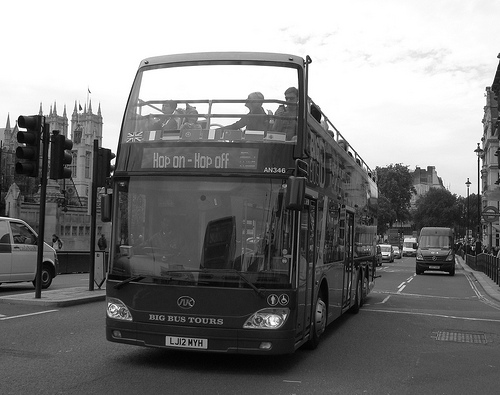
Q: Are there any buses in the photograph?
A: Yes, there is a bus.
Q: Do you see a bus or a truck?
A: Yes, there is a bus.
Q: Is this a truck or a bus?
A: This is a bus.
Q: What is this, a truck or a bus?
A: This is a bus.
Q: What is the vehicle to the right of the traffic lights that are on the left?
A: The vehicle is a bus.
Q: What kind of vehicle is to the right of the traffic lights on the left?
A: The vehicle is a bus.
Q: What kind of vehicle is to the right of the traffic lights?
A: The vehicle is a bus.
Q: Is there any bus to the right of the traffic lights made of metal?
A: Yes, there is a bus to the right of the traffic lights.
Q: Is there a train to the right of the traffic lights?
A: No, there is a bus to the right of the traffic lights.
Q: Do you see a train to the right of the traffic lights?
A: No, there is a bus to the right of the traffic lights.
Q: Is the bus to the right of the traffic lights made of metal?
A: Yes, the bus is to the right of the traffic lights.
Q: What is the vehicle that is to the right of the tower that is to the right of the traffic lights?
A: The vehicle is a bus.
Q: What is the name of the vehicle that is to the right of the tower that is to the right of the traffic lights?
A: The vehicle is a bus.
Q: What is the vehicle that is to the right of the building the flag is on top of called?
A: The vehicle is a bus.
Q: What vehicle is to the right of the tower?
A: The vehicle is a bus.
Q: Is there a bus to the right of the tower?
A: Yes, there is a bus to the right of the tower.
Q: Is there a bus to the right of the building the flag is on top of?
A: Yes, there is a bus to the right of the tower.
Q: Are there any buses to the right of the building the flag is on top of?
A: Yes, there is a bus to the right of the tower.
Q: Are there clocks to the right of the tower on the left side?
A: No, there is a bus to the right of the tower.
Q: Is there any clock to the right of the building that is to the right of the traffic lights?
A: No, there is a bus to the right of the tower.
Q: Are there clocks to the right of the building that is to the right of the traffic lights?
A: No, there is a bus to the right of the tower.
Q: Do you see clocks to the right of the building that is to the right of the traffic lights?
A: No, there is a bus to the right of the tower.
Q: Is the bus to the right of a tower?
A: Yes, the bus is to the right of a tower.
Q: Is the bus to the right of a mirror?
A: No, the bus is to the right of a tower.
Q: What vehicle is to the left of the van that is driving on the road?
A: The vehicle is a bus.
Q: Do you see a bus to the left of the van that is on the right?
A: Yes, there is a bus to the left of the van.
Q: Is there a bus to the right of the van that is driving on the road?
A: No, the bus is to the left of the van.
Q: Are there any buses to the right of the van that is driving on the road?
A: No, the bus is to the left of the van.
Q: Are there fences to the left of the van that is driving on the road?
A: No, there is a bus to the left of the van.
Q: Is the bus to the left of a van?
A: Yes, the bus is to the left of a van.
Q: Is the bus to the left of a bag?
A: No, the bus is to the left of a van.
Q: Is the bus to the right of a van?
A: No, the bus is to the left of a van.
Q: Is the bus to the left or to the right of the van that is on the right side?
A: The bus is to the left of the van.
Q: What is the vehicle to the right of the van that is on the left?
A: The vehicle is a bus.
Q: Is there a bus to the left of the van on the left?
A: No, the bus is to the right of the van.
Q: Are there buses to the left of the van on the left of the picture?
A: No, the bus is to the right of the van.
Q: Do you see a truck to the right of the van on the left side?
A: No, there is a bus to the right of the van.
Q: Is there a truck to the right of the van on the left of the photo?
A: No, there is a bus to the right of the van.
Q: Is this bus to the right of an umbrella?
A: No, the bus is to the right of a van.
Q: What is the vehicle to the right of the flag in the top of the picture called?
A: The vehicle is a bus.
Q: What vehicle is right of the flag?
A: The vehicle is a bus.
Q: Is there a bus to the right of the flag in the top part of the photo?
A: Yes, there is a bus to the right of the flag.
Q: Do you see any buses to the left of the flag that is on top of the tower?
A: No, the bus is to the right of the flag.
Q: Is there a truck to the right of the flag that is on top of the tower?
A: No, there is a bus to the right of the flag.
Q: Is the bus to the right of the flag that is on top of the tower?
A: Yes, the bus is to the right of the flag.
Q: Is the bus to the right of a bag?
A: No, the bus is to the right of the flag.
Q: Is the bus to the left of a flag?
A: No, the bus is to the right of a flag.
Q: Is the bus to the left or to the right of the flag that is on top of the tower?
A: The bus is to the right of the flag.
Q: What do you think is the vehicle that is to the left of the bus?
A: The vehicle is a van.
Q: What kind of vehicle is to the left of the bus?
A: The vehicle is a van.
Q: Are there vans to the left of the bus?
A: Yes, there is a van to the left of the bus.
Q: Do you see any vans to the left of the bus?
A: Yes, there is a van to the left of the bus.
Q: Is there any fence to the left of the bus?
A: No, there is a van to the left of the bus.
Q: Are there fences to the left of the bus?
A: No, there is a van to the left of the bus.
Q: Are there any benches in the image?
A: No, there are no benches.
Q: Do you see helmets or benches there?
A: No, there are no benches or helmets.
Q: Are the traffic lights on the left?
A: Yes, the traffic lights are on the left of the image.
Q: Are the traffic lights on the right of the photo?
A: No, the traffic lights are on the left of the image.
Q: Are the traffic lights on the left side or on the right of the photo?
A: The traffic lights are on the left of the image.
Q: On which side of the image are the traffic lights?
A: The traffic lights are on the left of the image.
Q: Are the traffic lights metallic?
A: Yes, the traffic lights are metallic.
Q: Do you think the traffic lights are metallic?
A: Yes, the traffic lights are metallic.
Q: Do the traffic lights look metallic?
A: Yes, the traffic lights are metallic.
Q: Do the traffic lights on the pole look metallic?
A: Yes, the traffic lights are metallic.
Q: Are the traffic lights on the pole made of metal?
A: Yes, the traffic lights are made of metal.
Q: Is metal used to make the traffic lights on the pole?
A: Yes, the traffic lights are made of metal.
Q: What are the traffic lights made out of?
A: The traffic lights are made of metal.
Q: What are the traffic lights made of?
A: The traffic lights are made of metal.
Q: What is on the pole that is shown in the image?
A: The traffic lights are on the pole.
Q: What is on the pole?
A: The traffic lights are on the pole.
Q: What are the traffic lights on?
A: The traffic lights are on the pole.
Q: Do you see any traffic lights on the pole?
A: Yes, there are traffic lights on the pole.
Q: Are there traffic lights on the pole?
A: Yes, there are traffic lights on the pole.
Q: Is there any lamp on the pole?
A: No, there are traffic lights on the pole.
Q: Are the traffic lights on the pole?
A: Yes, the traffic lights are on the pole.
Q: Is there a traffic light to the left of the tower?
A: Yes, there are traffic lights to the left of the tower.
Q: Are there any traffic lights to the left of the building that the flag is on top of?
A: Yes, there are traffic lights to the left of the tower.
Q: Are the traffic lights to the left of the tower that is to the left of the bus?
A: Yes, the traffic lights are to the left of the tower.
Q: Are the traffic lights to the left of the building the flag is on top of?
A: Yes, the traffic lights are to the left of the tower.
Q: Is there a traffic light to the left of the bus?
A: Yes, there are traffic lights to the left of the bus.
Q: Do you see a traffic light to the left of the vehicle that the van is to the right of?
A: Yes, there are traffic lights to the left of the bus.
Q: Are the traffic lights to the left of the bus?
A: Yes, the traffic lights are to the left of the bus.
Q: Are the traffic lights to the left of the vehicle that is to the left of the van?
A: Yes, the traffic lights are to the left of the bus.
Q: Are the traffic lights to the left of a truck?
A: No, the traffic lights are to the left of the bus.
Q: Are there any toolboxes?
A: No, there are no toolboxes.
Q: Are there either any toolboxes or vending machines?
A: No, there are no toolboxes or vending machines.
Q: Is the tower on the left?
A: Yes, the tower is on the left of the image.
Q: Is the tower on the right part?
A: No, the tower is on the left of the image.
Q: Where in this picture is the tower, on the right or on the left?
A: The tower is on the left of the image.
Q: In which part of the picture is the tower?
A: The tower is on the left of the image.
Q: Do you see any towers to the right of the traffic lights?
A: Yes, there is a tower to the right of the traffic lights.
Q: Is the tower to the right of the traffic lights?
A: Yes, the tower is to the right of the traffic lights.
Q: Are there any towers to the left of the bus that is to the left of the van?
A: Yes, there is a tower to the left of the bus.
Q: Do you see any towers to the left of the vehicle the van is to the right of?
A: Yes, there is a tower to the left of the bus.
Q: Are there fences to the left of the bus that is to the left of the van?
A: No, there is a tower to the left of the bus.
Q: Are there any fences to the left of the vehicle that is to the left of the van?
A: No, there is a tower to the left of the bus.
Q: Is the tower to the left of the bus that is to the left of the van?
A: Yes, the tower is to the left of the bus.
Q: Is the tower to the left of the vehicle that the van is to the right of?
A: Yes, the tower is to the left of the bus.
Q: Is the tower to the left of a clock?
A: No, the tower is to the left of the bus.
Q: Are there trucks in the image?
A: No, there are no trucks.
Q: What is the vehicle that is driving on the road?
A: The vehicle is a van.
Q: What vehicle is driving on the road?
A: The vehicle is a van.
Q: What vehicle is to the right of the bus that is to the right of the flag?
A: The vehicle is a van.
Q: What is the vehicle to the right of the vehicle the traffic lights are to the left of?
A: The vehicle is a van.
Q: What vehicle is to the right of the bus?
A: The vehicle is a van.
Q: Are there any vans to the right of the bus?
A: Yes, there is a van to the right of the bus.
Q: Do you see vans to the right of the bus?
A: Yes, there is a van to the right of the bus.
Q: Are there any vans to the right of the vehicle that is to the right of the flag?
A: Yes, there is a van to the right of the bus.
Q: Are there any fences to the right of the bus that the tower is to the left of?
A: No, there is a van to the right of the bus.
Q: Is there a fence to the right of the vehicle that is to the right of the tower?
A: No, there is a van to the right of the bus.